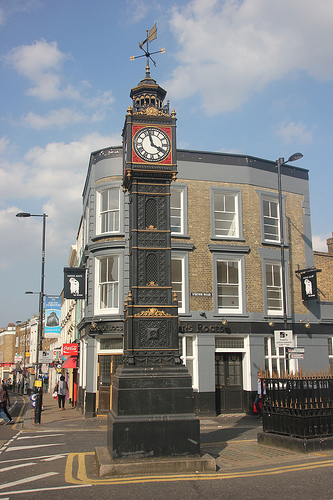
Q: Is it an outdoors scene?
A: Yes, it is outdoors.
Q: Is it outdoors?
A: Yes, it is outdoors.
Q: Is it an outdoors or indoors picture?
A: It is outdoors.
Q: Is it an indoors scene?
A: No, it is outdoors.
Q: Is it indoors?
A: No, it is outdoors.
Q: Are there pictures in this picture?
A: No, there are no pictures.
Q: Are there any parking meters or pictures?
A: No, there are no pictures or parking meters.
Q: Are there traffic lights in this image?
A: No, there are no traffic lights.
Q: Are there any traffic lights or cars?
A: No, there are no traffic lights or cars.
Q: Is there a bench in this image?
A: No, there are no benches.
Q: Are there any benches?
A: No, there are no benches.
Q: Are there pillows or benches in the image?
A: No, there are no benches or pillows.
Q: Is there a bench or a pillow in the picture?
A: No, there are no benches or pillows.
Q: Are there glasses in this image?
A: No, there are no glasses.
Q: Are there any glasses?
A: No, there are no glasses.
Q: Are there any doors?
A: Yes, there is a door.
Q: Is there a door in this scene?
A: Yes, there is a door.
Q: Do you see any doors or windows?
A: Yes, there is a door.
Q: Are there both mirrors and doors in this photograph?
A: No, there is a door but no mirrors.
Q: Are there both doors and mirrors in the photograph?
A: No, there is a door but no mirrors.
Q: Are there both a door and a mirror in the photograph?
A: No, there is a door but no mirrors.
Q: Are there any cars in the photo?
A: No, there are no cars.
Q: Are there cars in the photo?
A: No, there are no cars.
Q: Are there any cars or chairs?
A: No, there are no cars or chairs.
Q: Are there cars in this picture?
A: No, there are no cars.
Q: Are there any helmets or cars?
A: No, there are no cars or helmets.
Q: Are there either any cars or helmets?
A: No, there are no cars or helmets.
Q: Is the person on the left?
A: Yes, the person is on the left of the image.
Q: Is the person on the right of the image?
A: No, the person is on the left of the image.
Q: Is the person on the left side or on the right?
A: The person is on the left of the image.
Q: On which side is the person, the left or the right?
A: The person is on the left of the image.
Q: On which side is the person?
A: The person is on the left of the image.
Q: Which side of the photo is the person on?
A: The person is on the left of the image.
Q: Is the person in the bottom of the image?
A: Yes, the person is in the bottom of the image.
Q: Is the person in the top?
A: No, the person is in the bottom of the image.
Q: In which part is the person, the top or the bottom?
A: The person is in the bottom of the image.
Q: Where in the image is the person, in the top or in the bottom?
A: The person is in the bottom of the image.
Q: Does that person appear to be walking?
A: Yes, the person is walking.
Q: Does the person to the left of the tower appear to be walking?
A: Yes, the person is walking.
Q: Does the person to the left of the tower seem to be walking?
A: Yes, the person is walking.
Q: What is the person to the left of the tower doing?
A: The person is walking.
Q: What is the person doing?
A: The person is walking.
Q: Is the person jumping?
A: No, the person is walking.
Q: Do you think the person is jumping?
A: No, the person is walking.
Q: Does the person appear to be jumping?
A: No, the person is walking.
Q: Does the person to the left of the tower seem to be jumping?
A: No, the person is walking.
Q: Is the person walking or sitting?
A: The person is walking.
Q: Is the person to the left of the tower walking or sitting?
A: The person is walking.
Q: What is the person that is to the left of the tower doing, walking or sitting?
A: The person is walking.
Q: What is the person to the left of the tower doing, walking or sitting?
A: The person is walking.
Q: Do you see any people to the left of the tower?
A: Yes, there is a person to the left of the tower.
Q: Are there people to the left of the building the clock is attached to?
A: Yes, there is a person to the left of the tower.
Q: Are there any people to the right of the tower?
A: No, the person is to the left of the tower.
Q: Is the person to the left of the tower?
A: Yes, the person is to the left of the tower.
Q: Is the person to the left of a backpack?
A: No, the person is to the left of the tower.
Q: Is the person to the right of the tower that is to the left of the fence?
A: No, the person is to the left of the tower.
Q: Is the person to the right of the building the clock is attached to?
A: No, the person is to the left of the tower.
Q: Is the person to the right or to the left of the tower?
A: The person is to the left of the tower.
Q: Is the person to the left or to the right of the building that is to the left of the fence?
A: The person is to the left of the tower.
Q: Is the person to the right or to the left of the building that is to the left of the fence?
A: The person is to the left of the tower.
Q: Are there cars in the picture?
A: No, there are no cars.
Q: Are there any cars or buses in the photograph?
A: No, there are no cars or buses.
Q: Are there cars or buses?
A: No, there are no cars or buses.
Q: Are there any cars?
A: No, there are no cars.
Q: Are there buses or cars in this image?
A: No, there are no cars or buses.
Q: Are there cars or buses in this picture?
A: No, there are no cars or buses.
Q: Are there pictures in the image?
A: No, there are no pictures.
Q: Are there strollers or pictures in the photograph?
A: No, there are no pictures or strollers.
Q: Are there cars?
A: No, there are no cars.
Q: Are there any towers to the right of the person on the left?
A: Yes, there is a tower to the right of the person.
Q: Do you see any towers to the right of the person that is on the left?
A: Yes, there is a tower to the right of the person.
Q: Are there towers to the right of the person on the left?
A: Yes, there is a tower to the right of the person.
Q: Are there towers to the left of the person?
A: No, the tower is to the right of the person.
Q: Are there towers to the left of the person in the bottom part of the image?
A: No, the tower is to the right of the person.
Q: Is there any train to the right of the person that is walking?
A: No, there is a tower to the right of the person.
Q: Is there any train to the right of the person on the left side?
A: No, there is a tower to the right of the person.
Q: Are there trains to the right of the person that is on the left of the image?
A: No, there is a tower to the right of the person.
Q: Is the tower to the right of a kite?
A: No, the tower is to the right of the person.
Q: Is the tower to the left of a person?
A: No, the tower is to the right of a person.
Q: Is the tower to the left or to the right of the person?
A: The tower is to the right of the person.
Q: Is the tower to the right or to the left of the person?
A: The tower is to the right of the person.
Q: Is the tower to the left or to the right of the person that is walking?
A: The tower is to the right of the person.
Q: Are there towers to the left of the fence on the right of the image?
A: Yes, there is a tower to the left of the fence.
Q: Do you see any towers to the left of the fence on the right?
A: Yes, there is a tower to the left of the fence.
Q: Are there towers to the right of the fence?
A: No, the tower is to the left of the fence.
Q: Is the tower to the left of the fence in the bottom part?
A: Yes, the tower is to the left of the fence.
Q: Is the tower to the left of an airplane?
A: No, the tower is to the left of the fence.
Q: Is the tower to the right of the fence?
A: No, the tower is to the left of the fence.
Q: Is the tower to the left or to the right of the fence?
A: The tower is to the left of the fence.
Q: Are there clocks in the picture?
A: Yes, there is a clock.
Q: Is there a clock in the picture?
A: Yes, there is a clock.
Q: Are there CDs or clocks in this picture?
A: Yes, there is a clock.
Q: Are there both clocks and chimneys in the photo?
A: No, there is a clock but no chimneys.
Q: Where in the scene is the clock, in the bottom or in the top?
A: The clock is in the top of the image.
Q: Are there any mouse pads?
A: No, there are no mouse pads.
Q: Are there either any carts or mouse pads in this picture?
A: No, there are no mouse pads or carts.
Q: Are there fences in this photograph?
A: Yes, there is a fence.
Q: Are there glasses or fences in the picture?
A: Yes, there is a fence.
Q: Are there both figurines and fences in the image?
A: No, there is a fence but no figurines.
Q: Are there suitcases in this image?
A: No, there are no suitcases.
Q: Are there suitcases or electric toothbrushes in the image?
A: No, there are no suitcases or electric toothbrushes.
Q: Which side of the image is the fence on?
A: The fence is on the right of the image.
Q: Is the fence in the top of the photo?
A: No, the fence is in the bottom of the image.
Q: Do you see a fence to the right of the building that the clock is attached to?
A: Yes, there is a fence to the right of the tower.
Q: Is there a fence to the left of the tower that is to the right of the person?
A: No, the fence is to the right of the tower.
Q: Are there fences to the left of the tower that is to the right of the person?
A: No, the fence is to the right of the tower.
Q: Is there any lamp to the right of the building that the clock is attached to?
A: No, there is a fence to the right of the tower.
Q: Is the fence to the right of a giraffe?
A: No, the fence is to the right of a tower.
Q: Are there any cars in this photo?
A: No, there are no cars.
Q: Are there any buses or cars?
A: No, there are no cars or buses.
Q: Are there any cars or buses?
A: No, there are no cars or buses.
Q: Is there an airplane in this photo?
A: No, there are no airplanes.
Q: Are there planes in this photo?
A: No, there are no planes.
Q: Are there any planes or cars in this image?
A: No, there are no planes or cars.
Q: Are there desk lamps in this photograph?
A: No, there are no desk lamps.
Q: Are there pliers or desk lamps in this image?
A: No, there are no desk lamps or pliers.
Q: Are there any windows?
A: Yes, there is a window.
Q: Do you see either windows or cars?
A: Yes, there is a window.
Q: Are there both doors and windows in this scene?
A: Yes, there are both a window and a door.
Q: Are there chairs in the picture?
A: No, there are no chairs.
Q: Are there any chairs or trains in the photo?
A: No, there are no chairs or trains.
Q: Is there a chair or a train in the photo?
A: No, there are no chairs or trains.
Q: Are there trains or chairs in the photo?
A: No, there are no chairs or trains.